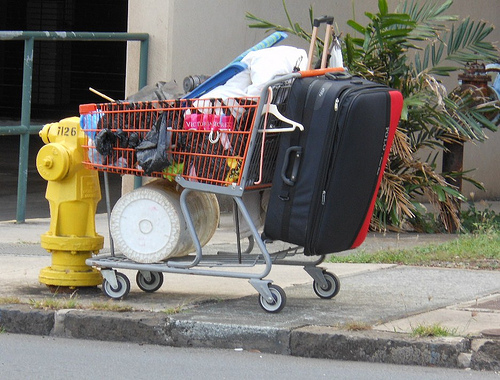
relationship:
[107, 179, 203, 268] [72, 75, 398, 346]
bucket in buggy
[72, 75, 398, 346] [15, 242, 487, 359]
buggy at sidewalk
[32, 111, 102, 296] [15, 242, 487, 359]
fire hydrant at sidewalk